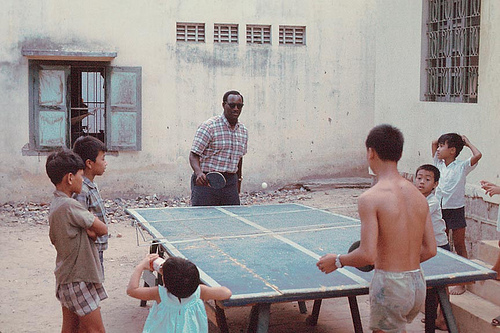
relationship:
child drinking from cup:
[121, 252, 228, 331] [141, 249, 168, 274]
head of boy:
[73, 135, 108, 176] [45, 148, 110, 330]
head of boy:
[45, 149, 85, 196] [68, 134, 110, 278]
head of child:
[76, 131, 111, 182] [68, 130, 111, 330]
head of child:
[414, 163, 441, 196] [400, 157, 457, 254]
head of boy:
[434, 130, 463, 163] [429, 131, 480, 295]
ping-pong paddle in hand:
[199, 170, 228, 191] [193, 172, 210, 188]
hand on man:
[193, 172, 210, 188] [189, 90, 247, 205]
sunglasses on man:
[224, 101, 244, 108] [186, 90, 253, 207]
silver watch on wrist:
[335, 250, 344, 269] [333, 253, 351, 268]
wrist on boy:
[333, 253, 351, 268] [315, 123, 440, 331]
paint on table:
[234, 257, 288, 289] [119, 196, 498, 328]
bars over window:
[429, 30, 474, 62] [417, 2, 487, 106]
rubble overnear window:
[99, 187, 169, 217] [18, 54, 180, 156]